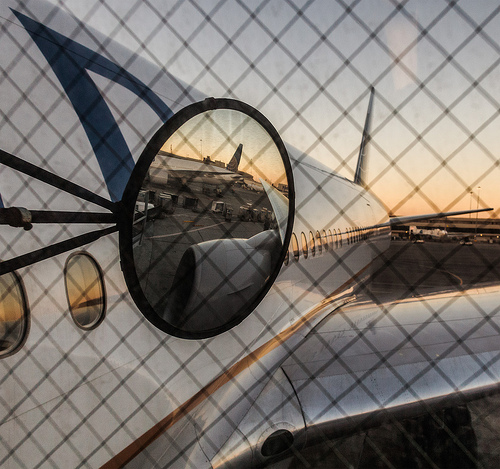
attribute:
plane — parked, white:
[14, 17, 489, 467]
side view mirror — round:
[117, 93, 294, 341]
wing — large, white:
[221, 279, 499, 456]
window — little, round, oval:
[61, 249, 112, 329]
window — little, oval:
[288, 231, 301, 263]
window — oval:
[300, 231, 310, 261]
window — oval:
[309, 230, 317, 258]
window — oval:
[315, 231, 324, 253]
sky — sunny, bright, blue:
[0, 0, 499, 220]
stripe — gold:
[19, 240, 390, 468]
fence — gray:
[1, 0, 500, 469]